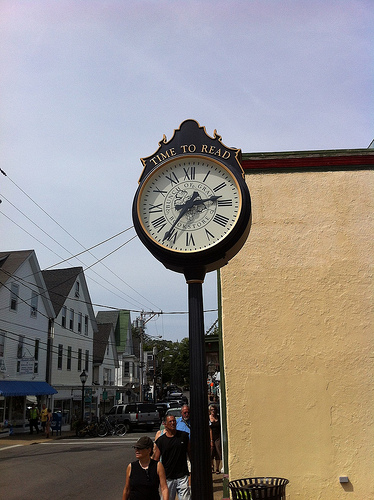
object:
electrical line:
[0, 222, 137, 312]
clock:
[134, 151, 242, 253]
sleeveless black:
[153, 434, 202, 469]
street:
[1, 389, 189, 496]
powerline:
[1, 168, 162, 310]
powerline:
[1, 210, 145, 311]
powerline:
[0, 265, 215, 313]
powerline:
[1, 316, 139, 346]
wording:
[144, 138, 234, 167]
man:
[153, 414, 189, 498]